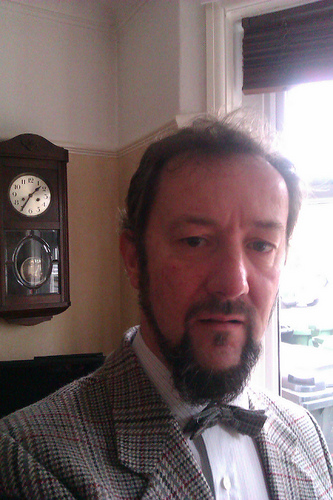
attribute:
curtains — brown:
[238, 0, 332, 95]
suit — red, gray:
[1, 323, 332, 499]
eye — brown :
[179, 233, 210, 248]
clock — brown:
[8, 173, 53, 218]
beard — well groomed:
[132, 262, 279, 408]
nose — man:
[201, 239, 266, 299]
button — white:
[221, 474, 232, 491]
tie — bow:
[183, 388, 272, 447]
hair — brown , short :
[118, 113, 274, 214]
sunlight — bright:
[278, 85, 331, 384]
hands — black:
[20, 195, 30, 210]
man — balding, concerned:
[0, 100, 332, 498]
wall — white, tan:
[19, 34, 141, 119]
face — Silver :
[14, 181, 42, 211]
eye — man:
[136, 190, 303, 296]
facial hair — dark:
[136, 294, 265, 404]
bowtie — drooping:
[179, 394, 306, 460]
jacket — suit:
[86, 384, 315, 483]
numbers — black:
[27, 206, 42, 214]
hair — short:
[138, 144, 307, 179]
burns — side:
[135, 240, 159, 344]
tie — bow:
[181, 402, 274, 445]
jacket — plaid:
[71, 398, 161, 487]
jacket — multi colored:
[77, 394, 150, 460]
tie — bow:
[181, 394, 280, 453]